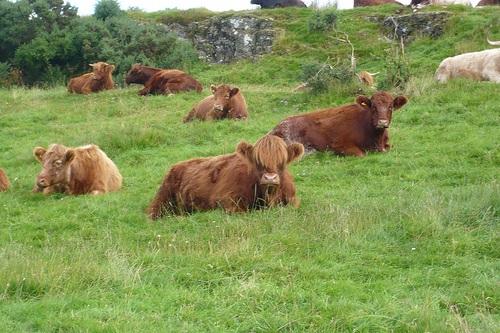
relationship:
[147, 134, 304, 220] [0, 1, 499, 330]
cow on grass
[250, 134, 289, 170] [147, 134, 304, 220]
thick hair on cow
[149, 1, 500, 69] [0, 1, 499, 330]
ledge has grass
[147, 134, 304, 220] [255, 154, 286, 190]
cow has a face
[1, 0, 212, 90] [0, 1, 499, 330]
bushes on grass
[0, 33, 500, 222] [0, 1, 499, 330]
animals on grass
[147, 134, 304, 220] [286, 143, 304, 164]
cow has an ear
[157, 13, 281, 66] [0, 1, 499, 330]
rock in grass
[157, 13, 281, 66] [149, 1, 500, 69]
rock on ledge